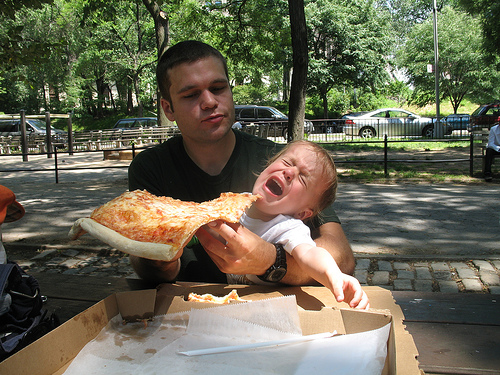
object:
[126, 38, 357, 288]
man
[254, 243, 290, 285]
watch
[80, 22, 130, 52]
leaves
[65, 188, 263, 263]
pizza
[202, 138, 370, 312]
child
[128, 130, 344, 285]
shirt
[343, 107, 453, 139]
car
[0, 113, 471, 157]
fence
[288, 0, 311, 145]
tree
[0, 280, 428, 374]
box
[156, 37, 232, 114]
hair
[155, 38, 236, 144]
head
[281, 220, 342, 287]
arm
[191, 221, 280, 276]
hand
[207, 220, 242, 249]
finger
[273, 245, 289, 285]
wrist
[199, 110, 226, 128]
mouth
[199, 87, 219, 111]
nose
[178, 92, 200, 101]
eye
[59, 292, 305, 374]
paper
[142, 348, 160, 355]
stains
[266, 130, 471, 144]
road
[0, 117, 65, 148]
car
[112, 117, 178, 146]
car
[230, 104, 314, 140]
car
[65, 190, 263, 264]
crust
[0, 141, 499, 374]
shadow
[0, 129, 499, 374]
ground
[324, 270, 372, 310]
hand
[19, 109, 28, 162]
pole